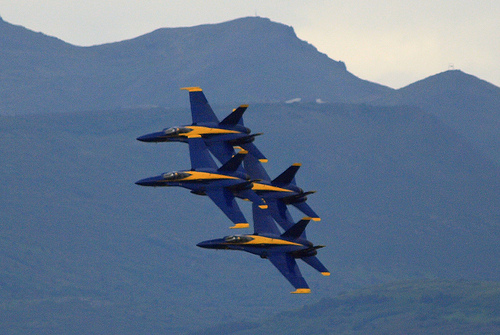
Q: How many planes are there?
A: 3.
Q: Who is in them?
A: Pilots.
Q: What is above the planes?
A: Skies.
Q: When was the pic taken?
A: During the day.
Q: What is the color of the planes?
A: Blue and yellow.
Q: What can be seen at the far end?
A: Hills.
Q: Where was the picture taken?
A: During the air show.